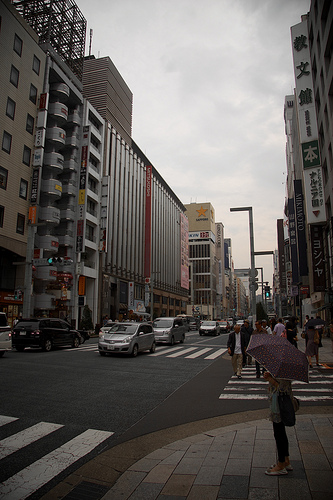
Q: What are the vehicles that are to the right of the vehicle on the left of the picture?
A: The vehicles are cars.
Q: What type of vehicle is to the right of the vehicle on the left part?
A: The vehicles are cars.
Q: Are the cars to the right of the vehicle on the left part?
A: Yes, the cars are to the right of the vehicle.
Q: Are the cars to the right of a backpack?
A: No, the cars are to the right of the vehicle.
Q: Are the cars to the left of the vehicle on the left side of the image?
A: No, the cars are to the right of the vehicle.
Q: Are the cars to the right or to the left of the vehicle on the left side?
A: The cars are to the right of the vehicle.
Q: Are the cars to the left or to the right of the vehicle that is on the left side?
A: The cars are to the right of the vehicle.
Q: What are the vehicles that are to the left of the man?
A: The vehicles are cars.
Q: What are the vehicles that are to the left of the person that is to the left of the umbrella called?
A: The vehicles are cars.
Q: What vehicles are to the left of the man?
A: The vehicles are cars.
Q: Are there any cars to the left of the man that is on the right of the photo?
A: Yes, there are cars to the left of the man.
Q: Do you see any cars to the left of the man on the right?
A: Yes, there are cars to the left of the man.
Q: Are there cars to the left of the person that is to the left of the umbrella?
A: Yes, there are cars to the left of the man.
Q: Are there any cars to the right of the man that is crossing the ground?
A: No, the cars are to the left of the man.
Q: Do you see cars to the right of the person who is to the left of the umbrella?
A: No, the cars are to the left of the man.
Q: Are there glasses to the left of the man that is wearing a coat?
A: No, there are cars to the left of the man.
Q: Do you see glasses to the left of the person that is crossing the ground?
A: No, there are cars to the left of the man.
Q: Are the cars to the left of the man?
A: Yes, the cars are to the left of the man.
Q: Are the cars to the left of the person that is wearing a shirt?
A: Yes, the cars are to the left of the man.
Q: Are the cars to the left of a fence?
A: No, the cars are to the left of the man.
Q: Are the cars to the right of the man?
A: No, the cars are to the left of the man.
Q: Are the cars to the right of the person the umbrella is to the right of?
A: No, the cars are to the left of the man.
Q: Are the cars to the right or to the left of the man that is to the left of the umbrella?
A: The cars are to the left of the man.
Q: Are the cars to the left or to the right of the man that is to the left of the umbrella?
A: The cars are to the left of the man.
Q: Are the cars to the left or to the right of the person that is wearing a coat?
A: The cars are to the left of the man.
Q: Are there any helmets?
A: No, there are no helmets.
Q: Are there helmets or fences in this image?
A: No, there are no helmets or fences.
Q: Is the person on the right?
A: Yes, the person is on the right of the image.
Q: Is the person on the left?
A: No, the person is on the right of the image.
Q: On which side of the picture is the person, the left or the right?
A: The person is on the right of the image.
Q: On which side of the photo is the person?
A: The person is on the right of the image.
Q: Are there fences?
A: No, there are no fences.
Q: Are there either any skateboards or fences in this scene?
A: No, there are no fences or skateboards.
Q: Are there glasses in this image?
A: No, there are no glasses.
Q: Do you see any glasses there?
A: No, there are no glasses.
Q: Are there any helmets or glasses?
A: No, there are no glasses or helmets.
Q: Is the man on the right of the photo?
A: Yes, the man is on the right of the image.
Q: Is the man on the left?
A: No, the man is on the right of the image.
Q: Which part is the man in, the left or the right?
A: The man is on the right of the image.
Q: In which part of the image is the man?
A: The man is on the right of the image.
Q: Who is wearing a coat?
A: The man is wearing a coat.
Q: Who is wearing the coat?
A: The man is wearing a coat.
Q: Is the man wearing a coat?
A: Yes, the man is wearing a coat.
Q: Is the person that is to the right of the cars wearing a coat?
A: Yes, the man is wearing a coat.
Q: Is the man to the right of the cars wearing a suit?
A: No, the man is wearing a coat.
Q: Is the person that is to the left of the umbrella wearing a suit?
A: No, the man is wearing a coat.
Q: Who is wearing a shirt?
A: The man is wearing a shirt.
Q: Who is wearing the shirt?
A: The man is wearing a shirt.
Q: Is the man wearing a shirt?
A: Yes, the man is wearing a shirt.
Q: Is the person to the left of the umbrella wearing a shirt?
A: Yes, the man is wearing a shirt.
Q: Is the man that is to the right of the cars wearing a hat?
A: No, the man is wearing a shirt.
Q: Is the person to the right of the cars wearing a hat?
A: No, the man is wearing a shirt.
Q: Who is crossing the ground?
A: The man is crossing the ground.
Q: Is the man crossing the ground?
A: Yes, the man is crossing the ground.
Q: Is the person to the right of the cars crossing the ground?
A: Yes, the man is crossing the ground.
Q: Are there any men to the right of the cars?
A: Yes, there is a man to the right of the cars.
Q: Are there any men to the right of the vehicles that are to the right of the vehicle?
A: Yes, there is a man to the right of the cars.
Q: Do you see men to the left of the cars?
A: No, the man is to the right of the cars.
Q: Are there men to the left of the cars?
A: No, the man is to the right of the cars.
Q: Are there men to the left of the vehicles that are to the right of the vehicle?
A: No, the man is to the right of the cars.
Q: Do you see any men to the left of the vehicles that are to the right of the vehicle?
A: No, the man is to the right of the cars.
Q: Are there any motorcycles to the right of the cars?
A: No, there is a man to the right of the cars.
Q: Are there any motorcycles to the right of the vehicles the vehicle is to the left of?
A: No, there is a man to the right of the cars.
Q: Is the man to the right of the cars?
A: Yes, the man is to the right of the cars.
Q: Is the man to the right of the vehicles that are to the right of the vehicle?
A: Yes, the man is to the right of the cars.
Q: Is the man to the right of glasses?
A: No, the man is to the right of the cars.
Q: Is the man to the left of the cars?
A: No, the man is to the right of the cars.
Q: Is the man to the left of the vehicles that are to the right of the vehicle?
A: No, the man is to the right of the cars.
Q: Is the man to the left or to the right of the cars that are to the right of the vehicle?
A: The man is to the right of the cars.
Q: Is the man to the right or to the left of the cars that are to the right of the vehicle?
A: The man is to the right of the cars.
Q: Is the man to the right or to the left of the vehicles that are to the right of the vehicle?
A: The man is to the right of the cars.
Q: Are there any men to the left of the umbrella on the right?
A: Yes, there is a man to the left of the umbrella.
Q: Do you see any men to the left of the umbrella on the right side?
A: Yes, there is a man to the left of the umbrella.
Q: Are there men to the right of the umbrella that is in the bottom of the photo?
A: No, the man is to the left of the umbrella.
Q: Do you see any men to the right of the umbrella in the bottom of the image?
A: No, the man is to the left of the umbrella.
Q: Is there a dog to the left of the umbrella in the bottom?
A: No, there is a man to the left of the umbrella.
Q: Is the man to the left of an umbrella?
A: Yes, the man is to the left of an umbrella.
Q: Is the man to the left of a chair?
A: No, the man is to the left of an umbrella.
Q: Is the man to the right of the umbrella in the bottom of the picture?
A: No, the man is to the left of the umbrella.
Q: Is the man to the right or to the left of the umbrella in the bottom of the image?
A: The man is to the left of the umbrella.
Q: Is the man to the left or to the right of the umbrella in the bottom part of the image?
A: The man is to the left of the umbrella.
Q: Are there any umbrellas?
A: Yes, there is an umbrella.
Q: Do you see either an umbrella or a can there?
A: Yes, there is an umbrella.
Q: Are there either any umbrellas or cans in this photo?
A: Yes, there is an umbrella.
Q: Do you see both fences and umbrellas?
A: No, there is an umbrella but no fences.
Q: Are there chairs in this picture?
A: No, there are no chairs.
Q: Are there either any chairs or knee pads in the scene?
A: No, there are no chairs or knee pads.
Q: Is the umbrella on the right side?
A: Yes, the umbrella is on the right of the image.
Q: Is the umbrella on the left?
A: No, the umbrella is on the right of the image.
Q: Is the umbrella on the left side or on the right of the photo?
A: The umbrella is on the right of the image.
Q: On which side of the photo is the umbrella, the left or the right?
A: The umbrella is on the right of the image.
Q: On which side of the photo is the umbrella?
A: The umbrella is on the right of the image.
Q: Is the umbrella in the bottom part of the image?
A: Yes, the umbrella is in the bottom of the image.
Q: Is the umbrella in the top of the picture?
A: No, the umbrella is in the bottom of the image.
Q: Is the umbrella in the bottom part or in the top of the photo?
A: The umbrella is in the bottom of the image.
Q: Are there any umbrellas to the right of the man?
A: Yes, there is an umbrella to the right of the man.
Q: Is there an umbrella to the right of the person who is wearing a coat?
A: Yes, there is an umbrella to the right of the man.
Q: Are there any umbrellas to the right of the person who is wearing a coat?
A: Yes, there is an umbrella to the right of the man.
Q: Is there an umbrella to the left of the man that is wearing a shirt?
A: No, the umbrella is to the right of the man.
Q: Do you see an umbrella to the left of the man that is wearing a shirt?
A: No, the umbrella is to the right of the man.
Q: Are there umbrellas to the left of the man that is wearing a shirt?
A: No, the umbrella is to the right of the man.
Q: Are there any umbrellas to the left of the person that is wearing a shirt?
A: No, the umbrella is to the right of the man.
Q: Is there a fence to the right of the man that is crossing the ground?
A: No, there is an umbrella to the right of the man.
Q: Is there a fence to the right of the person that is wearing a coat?
A: No, there is an umbrella to the right of the man.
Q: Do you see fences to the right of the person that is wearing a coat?
A: No, there is an umbrella to the right of the man.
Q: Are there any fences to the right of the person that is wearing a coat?
A: No, there is an umbrella to the right of the man.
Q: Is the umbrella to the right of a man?
A: Yes, the umbrella is to the right of a man.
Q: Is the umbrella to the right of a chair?
A: No, the umbrella is to the right of a man.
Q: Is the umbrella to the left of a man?
A: No, the umbrella is to the right of a man.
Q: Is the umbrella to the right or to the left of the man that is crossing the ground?
A: The umbrella is to the right of the man.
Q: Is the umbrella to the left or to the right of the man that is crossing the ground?
A: The umbrella is to the right of the man.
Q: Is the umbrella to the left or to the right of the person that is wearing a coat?
A: The umbrella is to the right of the man.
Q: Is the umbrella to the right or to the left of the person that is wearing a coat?
A: The umbrella is to the right of the man.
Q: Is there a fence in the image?
A: No, there are no fences.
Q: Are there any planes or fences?
A: No, there are no fences or planes.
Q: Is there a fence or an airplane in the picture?
A: No, there are no fences or airplanes.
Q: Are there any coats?
A: Yes, there is a coat.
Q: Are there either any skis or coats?
A: Yes, there is a coat.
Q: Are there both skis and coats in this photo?
A: No, there is a coat but no skis.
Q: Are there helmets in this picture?
A: No, there are no helmets.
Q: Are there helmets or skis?
A: No, there are no helmets or skis.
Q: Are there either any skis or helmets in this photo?
A: No, there are no helmets or skis.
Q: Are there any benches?
A: No, there are no benches.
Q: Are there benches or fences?
A: No, there are no benches or fences.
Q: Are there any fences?
A: No, there are no fences.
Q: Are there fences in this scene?
A: No, there are no fences.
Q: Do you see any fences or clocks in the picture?
A: No, there are no fences or clocks.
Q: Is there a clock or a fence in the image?
A: No, there are no fences or clocks.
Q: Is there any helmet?
A: No, there are no helmets.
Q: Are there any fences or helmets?
A: No, there are no helmets or fences.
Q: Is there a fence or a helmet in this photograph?
A: No, there are no helmets or fences.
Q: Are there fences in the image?
A: No, there are no fences.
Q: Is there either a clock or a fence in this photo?
A: No, there are no fences or clocks.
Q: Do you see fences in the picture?
A: No, there are no fences.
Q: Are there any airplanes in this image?
A: No, there are no airplanes.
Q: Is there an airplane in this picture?
A: No, there are no airplanes.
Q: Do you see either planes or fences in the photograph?
A: No, there are no planes or fences.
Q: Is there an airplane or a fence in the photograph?
A: No, there are no airplanes or fences.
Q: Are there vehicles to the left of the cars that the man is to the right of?
A: Yes, there is a vehicle to the left of the cars.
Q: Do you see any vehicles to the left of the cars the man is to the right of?
A: Yes, there is a vehicle to the left of the cars.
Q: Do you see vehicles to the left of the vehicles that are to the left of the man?
A: Yes, there is a vehicle to the left of the cars.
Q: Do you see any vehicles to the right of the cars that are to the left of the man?
A: No, the vehicle is to the left of the cars.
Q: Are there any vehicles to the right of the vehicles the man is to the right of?
A: No, the vehicle is to the left of the cars.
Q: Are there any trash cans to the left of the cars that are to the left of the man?
A: No, there is a vehicle to the left of the cars.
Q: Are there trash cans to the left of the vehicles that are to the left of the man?
A: No, there is a vehicle to the left of the cars.